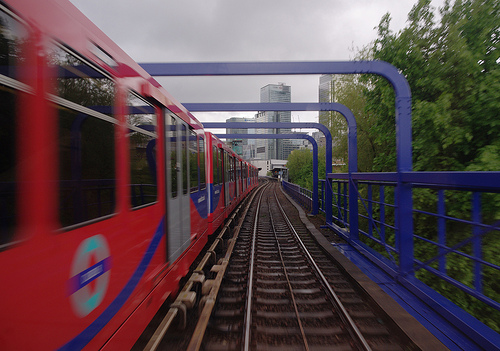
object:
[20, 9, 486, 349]
tracks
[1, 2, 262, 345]
train